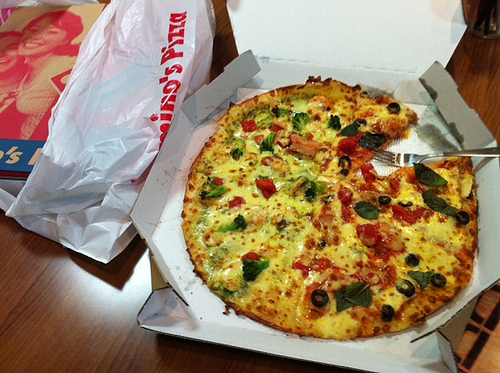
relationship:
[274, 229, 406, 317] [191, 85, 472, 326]
toppings on pizza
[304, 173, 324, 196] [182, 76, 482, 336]
olive on pie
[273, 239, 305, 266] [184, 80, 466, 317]
cheese on pie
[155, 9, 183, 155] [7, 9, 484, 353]
letters of shop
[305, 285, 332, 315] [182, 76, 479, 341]
olive on pie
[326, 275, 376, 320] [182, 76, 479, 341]
spinach on pie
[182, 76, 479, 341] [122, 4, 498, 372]
pie in box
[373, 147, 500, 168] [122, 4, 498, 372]
fork in box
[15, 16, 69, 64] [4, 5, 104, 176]
face on box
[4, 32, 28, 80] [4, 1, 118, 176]
face on box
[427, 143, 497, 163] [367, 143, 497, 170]
handle on fork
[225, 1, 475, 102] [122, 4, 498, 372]
top on box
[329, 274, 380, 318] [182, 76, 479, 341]
leaves stacked on pie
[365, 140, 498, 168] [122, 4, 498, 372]
fork in box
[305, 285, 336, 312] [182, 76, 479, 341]
olives on pie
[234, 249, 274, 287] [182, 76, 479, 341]
broccoli on pie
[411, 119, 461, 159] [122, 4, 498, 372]
stain in box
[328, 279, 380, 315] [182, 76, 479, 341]
spinach on pie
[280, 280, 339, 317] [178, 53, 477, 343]
olive on pizza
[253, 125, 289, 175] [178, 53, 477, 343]
broccoli on pizza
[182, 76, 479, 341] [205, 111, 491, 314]
pie with toppings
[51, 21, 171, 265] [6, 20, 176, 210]
bag next to a box